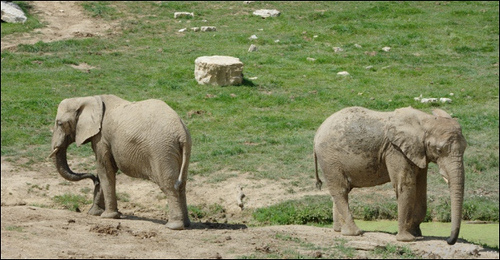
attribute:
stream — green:
[323, 200, 498, 257]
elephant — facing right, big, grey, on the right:
[309, 101, 471, 246]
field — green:
[0, 2, 497, 247]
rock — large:
[420, 95, 448, 105]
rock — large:
[0, 1, 27, 26]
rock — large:
[172, 11, 194, 18]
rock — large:
[252, 8, 279, 18]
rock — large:
[173, 25, 214, 33]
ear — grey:
[73, 96, 104, 148]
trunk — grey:
[435, 150, 469, 247]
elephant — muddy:
[305, 92, 483, 252]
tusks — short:
[42, 143, 66, 160]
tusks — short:
[434, 167, 451, 187]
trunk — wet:
[441, 151, 463, 245]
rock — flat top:
[192, 54, 247, 86]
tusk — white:
[427, 166, 469, 195]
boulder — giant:
[193, 54, 245, 90]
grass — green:
[0, 0, 498, 257]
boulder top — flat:
[190, 50, 246, 70]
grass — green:
[112, 52, 189, 97]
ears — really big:
[71, 95, 111, 148]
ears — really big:
[378, 99, 433, 171]